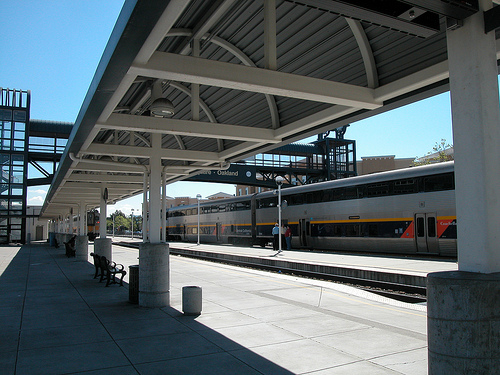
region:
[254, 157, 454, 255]
a silver double decker passenger train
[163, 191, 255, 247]
a silver double decker passenger train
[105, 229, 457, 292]
a passenger boarding platform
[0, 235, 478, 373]
a passenger boarding platform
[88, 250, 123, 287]
a black metal bench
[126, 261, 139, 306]
a black trash can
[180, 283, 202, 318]
a white trash can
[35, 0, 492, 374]
a train station protected shelter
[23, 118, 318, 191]
an overhead walkway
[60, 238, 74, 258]
a black trash can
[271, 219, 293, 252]
people standing beside train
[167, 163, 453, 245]
commuter train at station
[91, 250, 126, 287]
bench at the station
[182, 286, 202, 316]
trashcan at the train station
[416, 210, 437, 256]
entrance doors on train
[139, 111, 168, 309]
support columns for train station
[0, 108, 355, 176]
overhead walkway across tracks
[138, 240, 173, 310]
concrete base for columns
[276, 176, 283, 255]
lamppost on train platform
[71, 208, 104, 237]
commuter train arriving at station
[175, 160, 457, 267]
a passenger train on a train station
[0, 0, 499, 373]
train station is open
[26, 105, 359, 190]
a bridge over rails of train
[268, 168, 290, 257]
a light pole on a train platform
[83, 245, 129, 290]
a bench in front of train rails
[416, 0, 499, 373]
a column supporting a roof in train station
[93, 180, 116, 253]
a column near a bench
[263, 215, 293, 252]
people stand in front a door of train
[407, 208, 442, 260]
door of train is color gray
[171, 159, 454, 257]
train has a yellow line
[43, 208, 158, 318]
benches on the sidewalk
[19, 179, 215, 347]
benches on the sidewalk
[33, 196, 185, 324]
metal benches on the sidewalk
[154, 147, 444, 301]
a train at a station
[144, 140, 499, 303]
a silver train at a station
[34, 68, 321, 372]
benches under a pavalion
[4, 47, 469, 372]
benches under an awning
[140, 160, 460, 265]
subway train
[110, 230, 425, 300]
empty train-track at trainstop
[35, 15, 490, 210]
roof covering trainstop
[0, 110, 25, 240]
stairs leading to a bridge over trainstop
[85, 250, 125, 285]
empty metal bench at trainstop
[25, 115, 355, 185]
bridge over trainstop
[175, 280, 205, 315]
cement ashtray at trainstop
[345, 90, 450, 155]
blue sky during daytime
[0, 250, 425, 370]
pavement at trainstop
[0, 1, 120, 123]
blue sky at during daytime